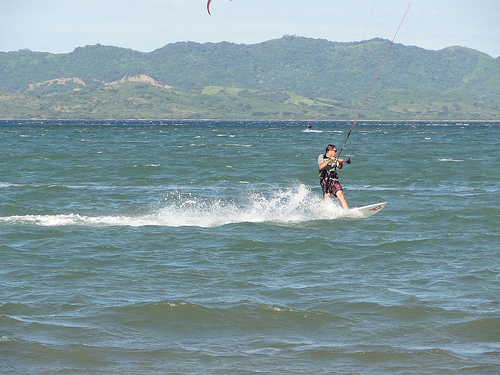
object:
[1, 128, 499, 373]
blue water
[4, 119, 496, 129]
dark water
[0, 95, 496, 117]
shore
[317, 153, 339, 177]
shirt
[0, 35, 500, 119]
trees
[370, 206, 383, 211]
logo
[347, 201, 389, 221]
board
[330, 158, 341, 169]
handle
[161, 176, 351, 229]
spray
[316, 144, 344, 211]
man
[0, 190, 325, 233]
wake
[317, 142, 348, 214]
wind surfer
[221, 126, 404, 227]
surfing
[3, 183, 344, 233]
white water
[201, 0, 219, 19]
kite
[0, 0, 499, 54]
sky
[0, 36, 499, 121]
hills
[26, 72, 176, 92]
stone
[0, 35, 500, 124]
land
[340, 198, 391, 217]
skies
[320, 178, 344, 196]
shorts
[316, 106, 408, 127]
shoreline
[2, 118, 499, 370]
water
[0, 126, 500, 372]
ocean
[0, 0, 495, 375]
air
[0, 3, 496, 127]
background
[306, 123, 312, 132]
person